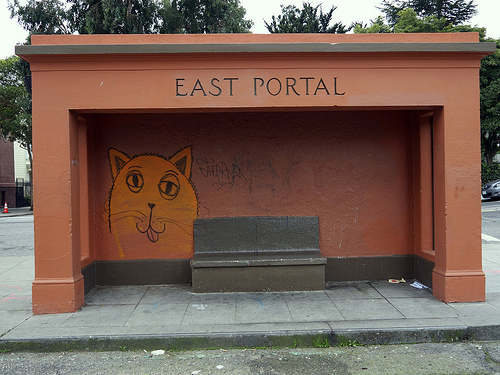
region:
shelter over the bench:
[22, 23, 496, 302]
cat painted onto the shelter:
[96, 134, 198, 263]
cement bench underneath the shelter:
[179, 210, 326, 281]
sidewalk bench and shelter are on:
[3, 218, 498, 327]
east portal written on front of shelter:
[157, 58, 348, 108]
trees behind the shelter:
[11, 3, 498, 204]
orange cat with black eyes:
[94, 120, 203, 261]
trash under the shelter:
[387, 274, 436, 303]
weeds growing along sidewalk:
[257, 334, 384, 353]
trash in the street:
[137, 343, 250, 374]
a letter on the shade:
[164, 65, 193, 105]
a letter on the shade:
[192, 72, 208, 102]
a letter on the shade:
[204, 65, 222, 105]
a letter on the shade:
[221, 74, 243, 99]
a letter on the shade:
[236, 65, 266, 105]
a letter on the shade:
[266, 66, 284, 97]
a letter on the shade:
[279, 73, 307, 102]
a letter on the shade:
[314, 70, 329, 104]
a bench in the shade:
[176, 212, 338, 288]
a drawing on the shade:
[89, 129, 206, 267]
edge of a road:
[303, 328, 345, 370]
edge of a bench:
[261, 248, 291, 278]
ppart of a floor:
[151, 290, 178, 325]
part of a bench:
[258, 250, 275, 269]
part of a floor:
[167, 291, 199, 336]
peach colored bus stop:
[14, 29, 489, 315]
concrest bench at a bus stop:
[188, 215, 328, 289]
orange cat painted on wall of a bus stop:
[105, 150, 204, 258]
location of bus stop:
[173, 76, 349, 97]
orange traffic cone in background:
[1, 201, 13, 214]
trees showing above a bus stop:
[8, 1, 475, 30]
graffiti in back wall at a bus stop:
[193, 151, 293, 193]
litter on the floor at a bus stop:
[384, 278, 429, 292]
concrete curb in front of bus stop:
[0, 322, 498, 350]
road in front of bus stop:
[0, 342, 496, 374]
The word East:
[168, 72, 242, 99]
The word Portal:
[250, 76, 350, 99]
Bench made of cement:
[188, 214, 330, 291]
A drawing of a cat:
[105, 146, 201, 269]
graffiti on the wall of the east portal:
[195, 150, 297, 202]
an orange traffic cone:
[2, 198, 10, 214]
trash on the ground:
[386, 275, 431, 294]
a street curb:
[3, 327, 499, 350]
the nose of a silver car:
[481, 176, 498, 201]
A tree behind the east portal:
[0, 51, 32, 154]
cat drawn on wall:
[95, 134, 217, 254]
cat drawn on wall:
[98, 129, 208, 261]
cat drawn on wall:
[99, 138, 211, 263]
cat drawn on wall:
[96, 133, 205, 266]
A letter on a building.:
[171, 73, 188, 103]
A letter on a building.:
[206, 76, 223, 99]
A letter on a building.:
[224, 73, 238, 94]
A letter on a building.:
[252, 75, 265, 94]